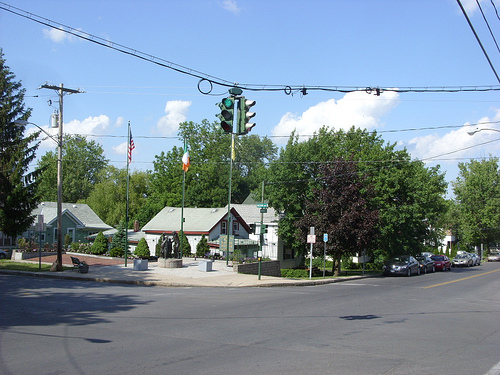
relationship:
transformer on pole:
[49, 108, 59, 126] [54, 82, 65, 272]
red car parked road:
[431, 251, 458, 276] [0, 259, 498, 373]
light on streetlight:
[222, 96, 233, 107] [218, 94, 260, 137]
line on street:
[406, 261, 491, 306] [1, 260, 498, 372]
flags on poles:
[117, 124, 139, 169] [116, 153, 135, 273]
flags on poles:
[173, 135, 198, 184] [172, 164, 194, 277]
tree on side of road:
[303, 157, 384, 281] [0, 259, 498, 373]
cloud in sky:
[270, 86, 400, 149] [226, 14, 488, 148]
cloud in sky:
[158, 96, 190, 134] [226, 14, 488, 148]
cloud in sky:
[412, 112, 498, 202] [226, 14, 488, 148]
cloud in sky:
[405, 108, 497, 202] [1, 0, 499, 200]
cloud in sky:
[270, 85, 400, 141] [1, 0, 499, 200]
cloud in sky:
[153, 97, 189, 140] [1, 0, 499, 200]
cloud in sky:
[24, 112, 130, 163] [1, 0, 499, 200]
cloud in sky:
[44, 24, 111, 45] [1, 0, 499, 200]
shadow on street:
[1, 272, 154, 329] [1, 260, 498, 372]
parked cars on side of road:
[373, 242, 483, 278] [9, 247, 499, 372]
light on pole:
[13, 110, 62, 153] [54, 82, 65, 272]